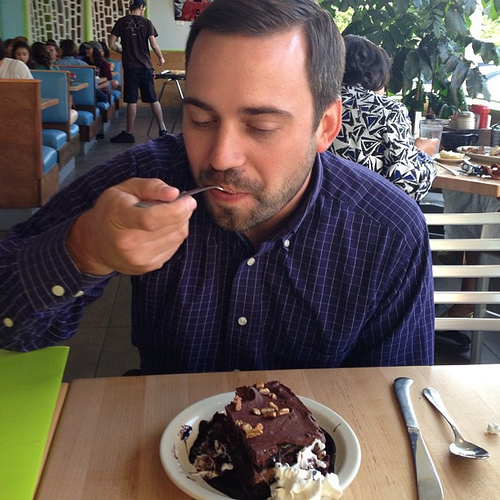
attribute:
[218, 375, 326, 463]
brownie — chocolate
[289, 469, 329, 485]
whipped cream — here, white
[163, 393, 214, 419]
plate — white, round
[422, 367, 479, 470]
spoon — silver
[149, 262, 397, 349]
shirt — black, blue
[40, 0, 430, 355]
man — eating, standing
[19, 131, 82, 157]
seats — blue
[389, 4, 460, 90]
plant — green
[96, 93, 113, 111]
chairs — blue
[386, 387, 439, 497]
knife — silver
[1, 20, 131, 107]
people — dining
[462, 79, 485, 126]
ketchup — bottle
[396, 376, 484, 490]
utensils — for eating, silver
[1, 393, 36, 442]
menu — green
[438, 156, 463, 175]
wrapper — straw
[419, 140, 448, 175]
paper — crumpled